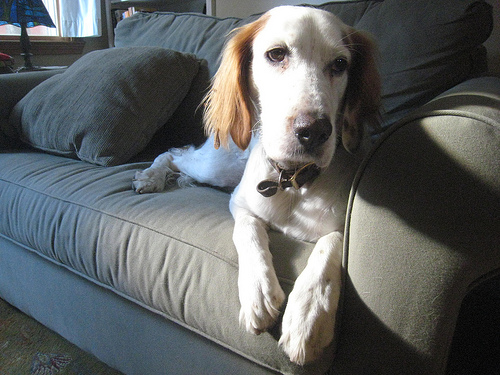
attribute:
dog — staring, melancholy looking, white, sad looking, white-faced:
[128, 4, 387, 365]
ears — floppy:
[197, 14, 387, 151]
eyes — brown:
[264, 42, 350, 77]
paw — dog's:
[276, 277, 340, 365]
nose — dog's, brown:
[293, 107, 336, 150]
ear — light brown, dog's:
[197, 14, 255, 158]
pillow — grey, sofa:
[4, 43, 202, 167]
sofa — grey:
[2, 0, 484, 372]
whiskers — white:
[330, 32, 372, 54]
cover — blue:
[14, 0, 60, 46]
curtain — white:
[60, 8, 107, 58]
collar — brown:
[262, 118, 323, 188]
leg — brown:
[193, 208, 353, 368]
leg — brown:
[173, 202, 283, 304]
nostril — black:
[297, 120, 305, 144]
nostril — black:
[313, 122, 338, 149]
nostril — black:
[299, 104, 335, 163]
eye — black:
[264, 19, 294, 95]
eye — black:
[317, 50, 370, 88]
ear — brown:
[199, 74, 277, 174]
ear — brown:
[347, 54, 392, 104]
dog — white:
[240, 84, 332, 225]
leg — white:
[142, 109, 206, 218]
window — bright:
[34, 25, 55, 73]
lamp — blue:
[17, 0, 53, 35]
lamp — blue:
[66, 66, 374, 310]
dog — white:
[178, 17, 411, 217]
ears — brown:
[165, 50, 240, 169]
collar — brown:
[281, 159, 321, 207]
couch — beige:
[77, 71, 120, 143]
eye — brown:
[251, 44, 300, 65]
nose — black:
[295, 110, 329, 139]